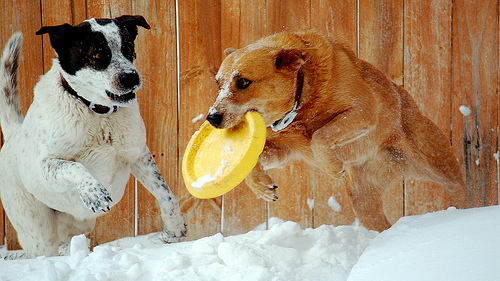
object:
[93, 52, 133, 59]
black eyes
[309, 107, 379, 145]
arm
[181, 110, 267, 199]
space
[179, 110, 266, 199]
disc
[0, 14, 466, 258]
dogs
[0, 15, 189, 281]
dog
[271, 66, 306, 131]
collar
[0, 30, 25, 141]
tail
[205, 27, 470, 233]
brown dog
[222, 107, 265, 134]
mouth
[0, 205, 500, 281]
snow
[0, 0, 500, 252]
fence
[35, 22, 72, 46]
ear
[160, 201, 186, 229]
legs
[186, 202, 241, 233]
water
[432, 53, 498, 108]
wood